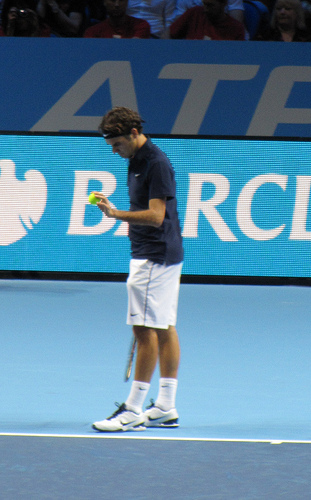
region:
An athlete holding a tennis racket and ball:
[89, 106, 185, 431]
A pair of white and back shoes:
[89, 404, 179, 432]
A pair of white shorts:
[125, 257, 181, 328]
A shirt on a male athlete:
[125, 137, 185, 264]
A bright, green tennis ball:
[87, 191, 101, 204]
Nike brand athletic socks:
[126, 376, 176, 411]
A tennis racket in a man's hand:
[124, 335, 135, 383]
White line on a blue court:
[0, 431, 306, 452]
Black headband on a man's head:
[101, 129, 142, 136]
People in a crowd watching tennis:
[0, 3, 307, 39]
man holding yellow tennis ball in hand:
[85, 190, 117, 218]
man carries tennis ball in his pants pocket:
[123, 256, 182, 330]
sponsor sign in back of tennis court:
[1, 135, 309, 280]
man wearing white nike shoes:
[91, 404, 179, 432]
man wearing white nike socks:
[123, 374, 177, 410]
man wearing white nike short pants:
[126, 257, 184, 333]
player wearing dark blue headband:
[97, 106, 147, 156]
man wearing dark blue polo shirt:
[126, 140, 185, 263]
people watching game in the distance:
[1, 0, 308, 45]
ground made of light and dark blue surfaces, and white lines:
[1, 417, 310, 469]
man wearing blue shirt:
[85, 106, 188, 427]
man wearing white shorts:
[93, 101, 181, 440]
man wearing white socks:
[96, 104, 201, 430]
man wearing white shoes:
[99, 115, 181, 430]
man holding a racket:
[89, 107, 176, 433]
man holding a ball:
[75, 112, 197, 438]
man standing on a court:
[87, 103, 225, 438]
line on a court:
[4, 429, 30, 440]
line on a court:
[62, 425, 88, 443]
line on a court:
[174, 432, 202, 447]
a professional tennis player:
[42, 59, 229, 450]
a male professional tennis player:
[71, 92, 215, 449]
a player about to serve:
[85, 95, 213, 444]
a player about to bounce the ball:
[56, 77, 202, 448]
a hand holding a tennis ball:
[73, 185, 124, 227]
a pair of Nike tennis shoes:
[80, 395, 194, 440]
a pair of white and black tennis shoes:
[75, 393, 196, 444]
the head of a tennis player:
[92, 99, 151, 165]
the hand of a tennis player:
[88, 185, 115, 229]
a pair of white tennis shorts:
[101, 250, 200, 334]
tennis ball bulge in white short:
[115, 266, 141, 296]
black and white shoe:
[90, 402, 142, 436]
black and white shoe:
[145, 401, 180, 427]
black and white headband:
[97, 113, 140, 138]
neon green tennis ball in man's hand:
[81, 189, 99, 209]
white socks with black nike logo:
[119, 377, 151, 410]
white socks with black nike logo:
[153, 375, 179, 409]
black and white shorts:
[123, 254, 184, 332]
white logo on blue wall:
[1, 156, 309, 271]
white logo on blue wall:
[32, 49, 309, 141]